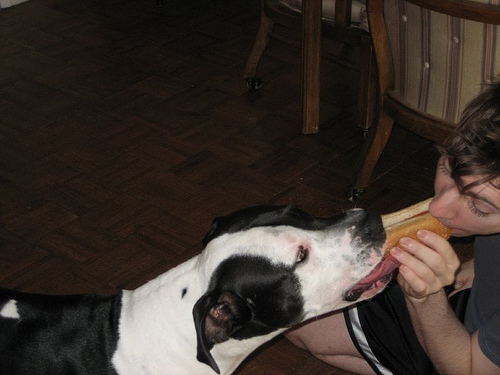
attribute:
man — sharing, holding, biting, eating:
[280, 81, 500, 374]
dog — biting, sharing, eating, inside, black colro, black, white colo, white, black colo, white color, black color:
[2, 202, 393, 373]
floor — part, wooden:
[1, 1, 477, 374]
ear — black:
[192, 291, 245, 374]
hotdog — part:
[385, 211, 453, 259]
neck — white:
[138, 266, 270, 374]